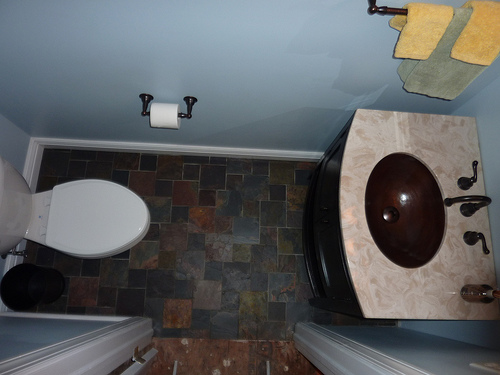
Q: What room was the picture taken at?
A: It was taken at the bathroom.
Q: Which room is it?
A: It is a bathroom.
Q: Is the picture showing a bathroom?
A: Yes, it is showing a bathroom.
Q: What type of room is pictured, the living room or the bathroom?
A: It is the bathroom.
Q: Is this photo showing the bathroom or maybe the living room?
A: It is showing the bathroom.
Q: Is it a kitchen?
A: No, it is a bathroom.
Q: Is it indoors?
A: Yes, it is indoors.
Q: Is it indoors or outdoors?
A: It is indoors.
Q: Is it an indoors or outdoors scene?
A: It is indoors.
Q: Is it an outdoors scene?
A: No, it is indoors.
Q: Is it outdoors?
A: No, it is indoors.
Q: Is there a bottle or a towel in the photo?
A: Yes, there is a towel.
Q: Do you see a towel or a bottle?
A: Yes, there is a towel.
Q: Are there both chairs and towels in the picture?
A: No, there is a towel but no chairs.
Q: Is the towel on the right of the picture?
A: Yes, the towel is on the right of the image.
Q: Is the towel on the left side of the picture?
A: No, the towel is on the right of the image.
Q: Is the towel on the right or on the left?
A: The towel is on the right of the image.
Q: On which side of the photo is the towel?
A: The towel is on the right of the image.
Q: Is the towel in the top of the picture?
A: Yes, the towel is in the top of the image.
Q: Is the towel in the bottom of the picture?
A: No, the towel is in the top of the image.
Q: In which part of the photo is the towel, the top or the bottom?
A: The towel is in the top of the image.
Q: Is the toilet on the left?
A: Yes, the toilet is on the left of the image.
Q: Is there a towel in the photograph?
A: Yes, there is a towel.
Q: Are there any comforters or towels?
A: Yes, there is a towel.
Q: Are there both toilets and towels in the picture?
A: Yes, there are both a towel and a toilet.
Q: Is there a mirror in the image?
A: No, there are no mirrors.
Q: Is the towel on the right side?
A: Yes, the towel is on the right of the image.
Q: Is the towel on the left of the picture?
A: No, the towel is on the right of the image.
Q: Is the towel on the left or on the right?
A: The towel is on the right of the image.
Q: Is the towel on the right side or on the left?
A: The towel is on the right of the image.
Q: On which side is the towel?
A: The towel is on the right of the image.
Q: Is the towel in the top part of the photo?
A: Yes, the towel is in the top of the image.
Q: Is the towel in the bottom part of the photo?
A: No, the towel is in the top of the image.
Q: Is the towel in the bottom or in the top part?
A: The towel is in the top of the image.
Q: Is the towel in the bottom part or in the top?
A: The towel is in the top of the image.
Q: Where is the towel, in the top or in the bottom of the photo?
A: The towel is in the top of the image.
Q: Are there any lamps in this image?
A: No, there are no lamps.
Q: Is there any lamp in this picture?
A: No, there are no lamps.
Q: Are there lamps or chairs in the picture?
A: No, there are no lamps or chairs.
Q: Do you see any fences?
A: No, there are no fences.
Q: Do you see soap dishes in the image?
A: No, there are no soap dishes.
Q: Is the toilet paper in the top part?
A: Yes, the toilet paper is in the top of the image.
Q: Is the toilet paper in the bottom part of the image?
A: No, the toilet paper is in the top of the image.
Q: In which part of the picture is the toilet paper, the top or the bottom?
A: The toilet paper is in the top of the image.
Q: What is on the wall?
A: The toilet paper is on the wall.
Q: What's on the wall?
A: The toilet paper is on the wall.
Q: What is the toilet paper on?
A: The toilet paper is on the wall.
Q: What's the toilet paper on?
A: The toilet paper is on the wall.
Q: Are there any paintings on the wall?
A: No, there is a toilet paper on the wall.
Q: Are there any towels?
A: Yes, there is a towel.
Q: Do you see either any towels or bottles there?
A: Yes, there is a towel.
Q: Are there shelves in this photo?
A: No, there are no shelves.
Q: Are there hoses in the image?
A: No, there are no hoses.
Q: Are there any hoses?
A: No, there are no hoses.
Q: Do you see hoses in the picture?
A: No, there are no hoses.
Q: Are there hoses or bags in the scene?
A: No, there are no hoses or bags.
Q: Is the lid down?
A: Yes, the lid is down.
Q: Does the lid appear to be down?
A: Yes, the lid is down.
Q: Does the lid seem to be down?
A: Yes, the lid is down.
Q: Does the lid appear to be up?
A: No, the lid is down.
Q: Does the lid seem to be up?
A: No, the lid is down.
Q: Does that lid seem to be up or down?
A: The lid is down.